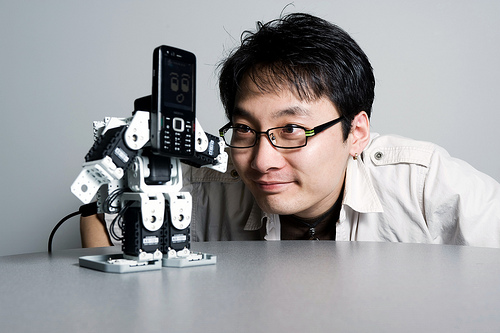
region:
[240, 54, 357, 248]
face of the person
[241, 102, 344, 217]
white face of the person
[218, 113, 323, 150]
spects of the person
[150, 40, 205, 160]
a old mobile phone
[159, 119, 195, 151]
key pad of the mobile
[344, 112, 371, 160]
ear of the person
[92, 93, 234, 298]
a small technical robo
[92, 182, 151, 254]
group of wires connecting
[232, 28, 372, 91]
hairs of the person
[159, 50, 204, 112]
display of the mobile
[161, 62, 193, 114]
THE ROBOT'S FACE IS A PHONE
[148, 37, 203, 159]
THE PHONE IS BLACK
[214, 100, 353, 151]
THE MAN IS WEARING GLASSES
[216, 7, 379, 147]
THE MAN HAS SHORT HAIR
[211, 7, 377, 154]
THE MAN'S HAIR IS BLACK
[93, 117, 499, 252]
THE MAN IS WEARING A JACKET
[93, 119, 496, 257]
THE MAN'S JACKET IS WHITE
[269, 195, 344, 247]
THE MAN IS WEARING A BROWN SHIRT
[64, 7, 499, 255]
THE MAN IS LOOKING AT THE ROBOT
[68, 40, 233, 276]
THE ROBOT IS BLACK AND WHITE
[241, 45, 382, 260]
a man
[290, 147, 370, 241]
a man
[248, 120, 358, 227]
a man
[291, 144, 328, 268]
a man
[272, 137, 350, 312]
a man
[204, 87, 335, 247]
a man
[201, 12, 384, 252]
man wearing black glasses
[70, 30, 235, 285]
robot with a phone face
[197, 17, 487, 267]
man in a white shirt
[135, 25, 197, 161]
black cellphone with white numbers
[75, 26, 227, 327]
black and white robot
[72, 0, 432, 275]
man looking at a robot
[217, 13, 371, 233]
man with short, black hair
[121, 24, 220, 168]
phone with a cartoon face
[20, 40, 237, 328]
robot on a gray table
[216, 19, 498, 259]
man in a light colored shirt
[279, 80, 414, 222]
a man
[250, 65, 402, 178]
a man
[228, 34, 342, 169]
a man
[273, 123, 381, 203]
a man